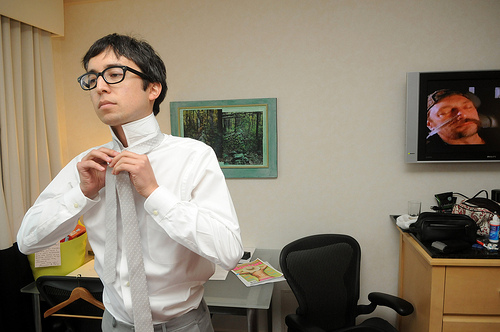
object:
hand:
[109, 151, 163, 198]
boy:
[10, 31, 242, 329]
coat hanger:
[40, 272, 106, 323]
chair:
[278, 227, 415, 332]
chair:
[33, 270, 105, 330]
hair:
[139, 57, 169, 80]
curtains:
[0, 16, 63, 253]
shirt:
[12, 110, 243, 326]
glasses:
[77, 65, 161, 92]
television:
[402, 70, 499, 162]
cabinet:
[389, 210, 499, 332]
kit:
[413, 213, 480, 243]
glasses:
[67, 63, 172, 105]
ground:
[400, 163, 432, 198]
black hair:
[92, 36, 111, 54]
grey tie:
[96, 126, 161, 330]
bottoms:
[103, 290, 213, 331]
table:
[203, 246, 280, 331]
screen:
[405, 67, 499, 162]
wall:
[53, 1, 498, 325]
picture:
[164, 95, 287, 178]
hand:
[75, 146, 117, 197]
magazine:
[229, 255, 291, 284]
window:
[1, 0, 66, 255]